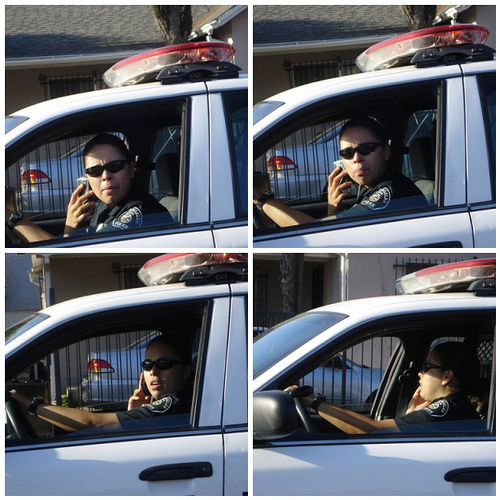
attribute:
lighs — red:
[354, 23, 487, 73]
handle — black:
[412, 238, 462, 250]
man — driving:
[253, 119, 431, 231]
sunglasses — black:
[339, 140, 386, 157]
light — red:
[104, 40, 237, 87]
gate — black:
[6, 132, 130, 219]